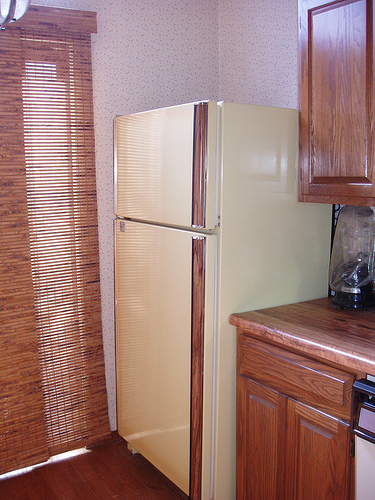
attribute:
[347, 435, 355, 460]
hinge — dark colored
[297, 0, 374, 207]
cabinets — wooden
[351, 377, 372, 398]
top — black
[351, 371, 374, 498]
dishwasher — white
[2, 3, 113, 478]
blinds — brown, long, wooden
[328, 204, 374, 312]
blender — black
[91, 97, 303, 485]
fridge —  white, combo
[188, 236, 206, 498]
wood — in strip 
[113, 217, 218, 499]
fridge door — of fridge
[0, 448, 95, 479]
light — sliver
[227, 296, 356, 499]
cabinet — brown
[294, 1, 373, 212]
cabinet — wooden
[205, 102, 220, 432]
strip — white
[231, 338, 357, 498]
cabinet — brown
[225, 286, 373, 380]
counter — wooden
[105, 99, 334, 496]
fridge — light yellow, yellow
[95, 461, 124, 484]
plank floor — wooden, of plank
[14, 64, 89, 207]
wooden blinds — brown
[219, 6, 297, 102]
wallpaper —  wall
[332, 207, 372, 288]
bag — plastic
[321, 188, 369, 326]
blending sitting — black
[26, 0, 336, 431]
wallpaper — flowered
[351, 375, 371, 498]
dishwasher — black, white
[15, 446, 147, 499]
floors — brown, hardwood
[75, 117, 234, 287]
refrigerator — cream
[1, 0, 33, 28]
light —  of ceiling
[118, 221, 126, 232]
sticker —  silver